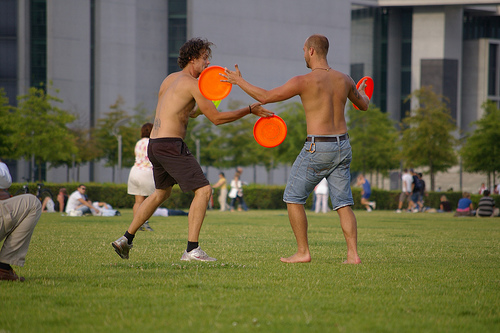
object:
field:
[1, 206, 498, 328]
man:
[217, 32, 374, 267]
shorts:
[280, 127, 357, 212]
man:
[62, 182, 101, 220]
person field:
[1, 157, 56, 297]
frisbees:
[346, 74, 378, 112]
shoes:
[179, 238, 215, 264]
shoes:
[0, 257, 25, 280]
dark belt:
[303, 130, 350, 146]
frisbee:
[194, 63, 233, 103]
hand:
[215, 63, 242, 86]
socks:
[122, 229, 137, 247]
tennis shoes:
[108, 235, 137, 262]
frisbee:
[249, 111, 291, 151]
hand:
[245, 101, 277, 119]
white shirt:
[401, 172, 415, 193]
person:
[391, 166, 418, 214]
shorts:
[143, 130, 210, 199]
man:
[108, 36, 276, 264]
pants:
[1, 188, 47, 283]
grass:
[47, 214, 123, 233]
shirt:
[64, 190, 88, 216]